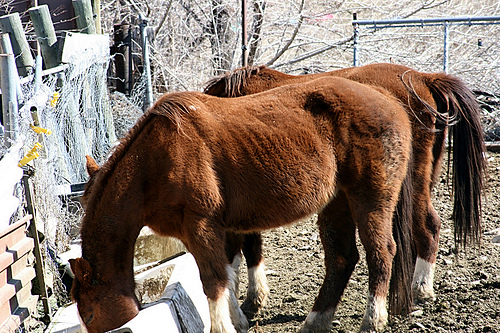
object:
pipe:
[29, 5, 61, 70]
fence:
[0, 175, 52, 332]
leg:
[179, 210, 235, 332]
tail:
[427, 74, 492, 258]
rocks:
[281, 293, 297, 303]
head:
[67, 257, 140, 332]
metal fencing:
[351, 12, 499, 150]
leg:
[240, 233, 269, 298]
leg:
[408, 140, 443, 292]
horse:
[67, 75, 414, 332]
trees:
[101, 0, 449, 75]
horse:
[200, 62, 491, 319]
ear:
[74, 257, 92, 288]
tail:
[389, 146, 415, 313]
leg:
[310, 190, 360, 311]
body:
[147, 74, 414, 332]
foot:
[240, 299, 267, 316]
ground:
[199, 145, 499, 331]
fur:
[222, 110, 309, 210]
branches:
[132, 39, 190, 91]